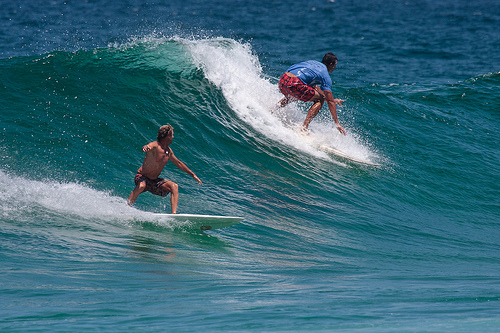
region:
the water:
[196, 239, 333, 319]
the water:
[276, 233, 296, 268]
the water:
[250, 262, 320, 327]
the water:
[253, 193, 279, 222]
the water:
[276, 190, 330, 301]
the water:
[304, 266, 339, 331]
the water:
[311, 171, 361, 290]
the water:
[270, 231, 305, 293]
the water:
[269, 189, 306, 256]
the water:
[248, 196, 319, 295]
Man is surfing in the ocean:
[112, 95, 254, 250]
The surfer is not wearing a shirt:
[130, 115, 202, 236]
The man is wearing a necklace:
[151, 137, 176, 164]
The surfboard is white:
[105, 195, 262, 262]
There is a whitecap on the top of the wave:
[148, 20, 254, 112]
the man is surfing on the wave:
[257, 51, 377, 171]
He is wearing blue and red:
[268, 52, 348, 134]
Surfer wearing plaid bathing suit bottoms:
[265, 66, 350, 122]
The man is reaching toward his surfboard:
[259, 38, 409, 194]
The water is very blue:
[299, 232, 414, 329]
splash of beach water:
[21, 132, 129, 240]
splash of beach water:
[64, 175, 135, 280]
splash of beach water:
[34, 172, 89, 236]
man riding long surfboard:
[126, 120, 201, 210]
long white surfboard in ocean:
[125, 205, 246, 220]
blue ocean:
[2, 0, 494, 330]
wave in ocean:
[0, 45, 495, 285]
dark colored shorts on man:
[127, 165, 174, 196]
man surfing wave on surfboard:
[271, 47, 346, 127]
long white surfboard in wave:
[285, 120, 375, 165]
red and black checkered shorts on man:
[275, 67, 320, 107]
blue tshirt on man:
[282, 51, 332, 87]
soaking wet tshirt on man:
[285, 55, 336, 88]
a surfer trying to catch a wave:
[190, 32, 402, 184]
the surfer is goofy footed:
[266, 47, 352, 147]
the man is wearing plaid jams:
[274, 71, 319, 109]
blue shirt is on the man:
[284, 55, 335, 97]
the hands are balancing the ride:
[311, 75, 357, 140]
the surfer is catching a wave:
[95, 116, 248, 238]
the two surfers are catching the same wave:
[60, 33, 378, 245]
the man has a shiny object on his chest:
[146, 123, 179, 168]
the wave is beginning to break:
[136, 27, 319, 165]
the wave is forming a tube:
[93, 24, 288, 148]